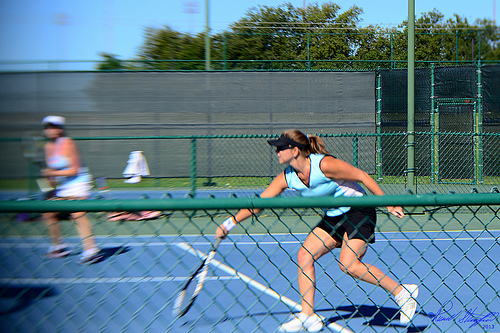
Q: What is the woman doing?
A: Swinging a tennis racket.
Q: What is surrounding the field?
A: Green chain link fence.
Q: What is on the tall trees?
A: Green leaves.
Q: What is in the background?
A: Green metal fence.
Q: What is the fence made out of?
A: Metal.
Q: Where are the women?
A: Tennis court.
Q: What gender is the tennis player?
A: Female.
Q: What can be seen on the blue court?
A: White lines.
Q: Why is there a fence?
A: To surround the court.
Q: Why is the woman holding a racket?
A: Playing tennis.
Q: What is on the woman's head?
A: Black visor.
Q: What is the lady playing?
A: Tennis.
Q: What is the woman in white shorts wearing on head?
A: Cap.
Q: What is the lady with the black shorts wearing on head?
A: Sun Visor.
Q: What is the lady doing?
A: Playing tennis.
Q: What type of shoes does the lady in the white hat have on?
A: Sneakers.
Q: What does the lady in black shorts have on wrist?
A: Wristband.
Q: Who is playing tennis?
A: 2 women.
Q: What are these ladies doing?
A: Playing tennis.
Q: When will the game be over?
A: Not sure.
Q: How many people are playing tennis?
A: 2.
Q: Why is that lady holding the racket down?
A: To hit the hall.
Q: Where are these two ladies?
A: Tennis court.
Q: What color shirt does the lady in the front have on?
A: Blue.